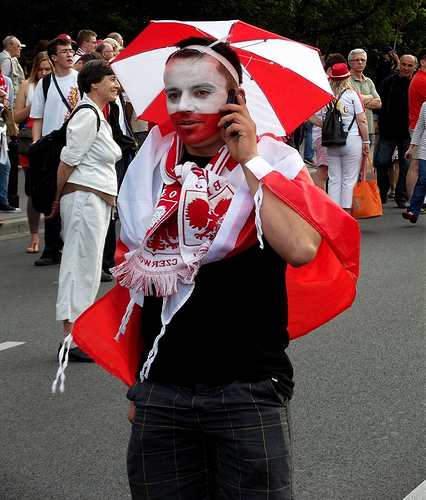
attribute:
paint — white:
[160, 58, 230, 116]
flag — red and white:
[57, 124, 361, 382]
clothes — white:
[48, 73, 306, 308]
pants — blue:
[120, 358, 293, 493]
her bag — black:
[267, 134, 318, 358]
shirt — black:
[127, 153, 293, 396]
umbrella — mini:
[103, 16, 332, 140]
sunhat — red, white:
[104, 17, 338, 140]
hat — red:
[325, 63, 354, 83]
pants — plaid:
[122, 371, 296, 498]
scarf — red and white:
[106, 131, 258, 296]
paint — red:
[173, 113, 208, 146]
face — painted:
[162, 55, 226, 146]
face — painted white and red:
[159, 52, 225, 141]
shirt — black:
[118, 182, 329, 349]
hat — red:
[114, 7, 330, 142]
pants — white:
[41, 187, 132, 316]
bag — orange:
[352, 151, 382, 217]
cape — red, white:
[69, 123, 359, 386]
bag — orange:
[350, 145, 383, 217]